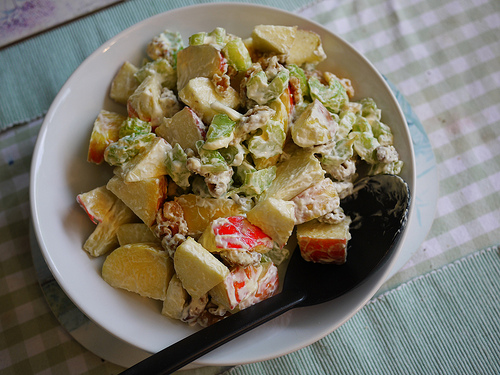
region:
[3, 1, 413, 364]
the bowl is round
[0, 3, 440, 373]
the bowl is white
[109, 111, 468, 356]
spoon in the bowl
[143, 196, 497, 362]
the spoon is black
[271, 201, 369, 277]
apple in the bowl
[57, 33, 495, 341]
the food has dressing on it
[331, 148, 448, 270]
dressing on the spoon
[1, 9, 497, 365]
the table cloth is green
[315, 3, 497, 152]
table cloth is checkered pattern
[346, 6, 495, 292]
table cloth is green and white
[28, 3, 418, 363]
Bowl of assorted vegetables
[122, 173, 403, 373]
Black spoon on top of the plate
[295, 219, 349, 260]
Piece of a cooked potato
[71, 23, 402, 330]
Assorted vegetables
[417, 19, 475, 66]
Checkered design of the mat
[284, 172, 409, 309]
Head of the spoon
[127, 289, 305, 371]
Handle of the spoon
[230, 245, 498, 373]
String design of the mat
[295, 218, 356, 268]
Potato on the spoon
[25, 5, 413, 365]
Plate with lunch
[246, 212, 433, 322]
Large black spoon on plate.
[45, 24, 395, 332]
Plate is underneath food.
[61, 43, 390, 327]
Plate is white in color.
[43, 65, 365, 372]
Plate is round in shape.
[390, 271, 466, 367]
Light blue place mat next to plate.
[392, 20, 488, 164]
Checkered table cloth on table.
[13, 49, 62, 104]
Light blue place mat near white plate.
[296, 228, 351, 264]
Piece of apple on plate.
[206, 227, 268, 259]
Red apple piece on plate.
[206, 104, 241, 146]
Piece of green grape on plate.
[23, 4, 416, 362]
bowl of apple salad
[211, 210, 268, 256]
a piece of apple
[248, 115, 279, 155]
a piece of celery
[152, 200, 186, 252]
a piece of roasted pecan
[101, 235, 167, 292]
a piece of apple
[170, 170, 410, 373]
a black serving spoon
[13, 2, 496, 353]
multicolored table cloth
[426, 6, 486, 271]
checkered green print part of table cloth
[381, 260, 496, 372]
green and white stripe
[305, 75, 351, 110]
chunk of green celery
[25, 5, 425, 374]
a white dish on a table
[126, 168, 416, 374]
a black spoon on a white dish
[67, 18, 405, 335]
a salad of vegetables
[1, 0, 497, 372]
a white dish over a table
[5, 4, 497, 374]
a tablecloth on a table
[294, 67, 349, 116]
piece of green celery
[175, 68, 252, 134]
slice of potatoe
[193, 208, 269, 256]
slice of apple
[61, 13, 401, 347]
vegetables are covered with mayonnaise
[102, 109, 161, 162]
pieces of celery